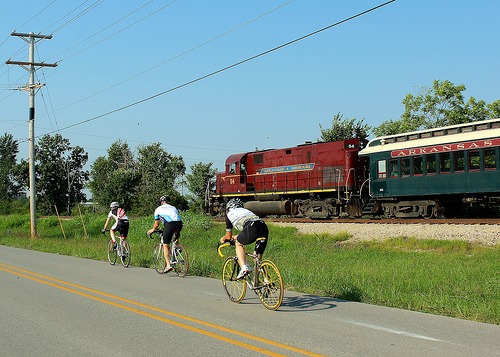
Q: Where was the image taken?
A: It was taken at the road.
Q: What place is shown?
A: It is a road.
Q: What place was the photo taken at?
A: It was taken at the road.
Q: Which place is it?
A: It is a road.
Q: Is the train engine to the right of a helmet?
A: Yes, the train engine is to the right of a helmet.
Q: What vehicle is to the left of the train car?
A: The vehicle is a locomotive.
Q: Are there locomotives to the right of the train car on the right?
A: No, the locomotive is to the left of the train car.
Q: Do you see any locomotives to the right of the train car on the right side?
A: No, the locomotive is to the left of the train car.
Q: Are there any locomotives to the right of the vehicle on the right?
A: No, the locomotive is to the left of the train car.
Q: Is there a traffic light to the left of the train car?
A: No, there is a locomotive to the left of the train car.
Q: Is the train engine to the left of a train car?
A: Yes, the train engine is to the left of a train car.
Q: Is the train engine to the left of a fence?
A: No, the train engine is to the left of a train car.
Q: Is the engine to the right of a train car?
A: No, the engine is to the left of a train car.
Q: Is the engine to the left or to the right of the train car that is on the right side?
A: The engine is to the left of the train car.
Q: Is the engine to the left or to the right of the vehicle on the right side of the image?
A: The engine is to the left of the train car.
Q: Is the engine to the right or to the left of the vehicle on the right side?
A: The engine is to the left of the train car.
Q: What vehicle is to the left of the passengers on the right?
A: The vehicle is a locomotive.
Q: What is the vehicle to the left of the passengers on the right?
A: The vehicle is a locomotive.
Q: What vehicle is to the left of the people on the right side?
A: The vehicle is a locomotive.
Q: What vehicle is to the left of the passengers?
A: The vehicle is a locomotive.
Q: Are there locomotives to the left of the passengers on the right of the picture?
A: Yes, there is a locomotive to the left of the passengers.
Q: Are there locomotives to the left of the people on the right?
A: Yes, there is a locomotive to the left of the passengers.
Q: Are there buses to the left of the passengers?
A: No, there is a locomotive to the left of the passengers.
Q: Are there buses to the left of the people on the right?
A: No, there is a locomotive to the left of the passengers.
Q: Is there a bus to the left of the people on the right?
A: No, there is a locomotive to the left of the passengers.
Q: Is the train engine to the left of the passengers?
A: Yes, the train engine is to the left of the passengers.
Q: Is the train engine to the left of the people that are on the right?
A: Yes, the train engine is to the left of the passengers.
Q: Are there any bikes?
A: Yes, there is a bike.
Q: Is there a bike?
A: Yes, there is a bike.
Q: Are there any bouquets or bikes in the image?
A: Yes, there is a bike.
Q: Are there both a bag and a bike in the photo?
A: No, there is a bike but no bags.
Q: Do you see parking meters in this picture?
A: No, there are no parking meters.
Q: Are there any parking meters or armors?
A: No, there are no parking meters or armors.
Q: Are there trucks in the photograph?
A: No, there are no trucks.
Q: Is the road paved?
A: Yes, the road is paved.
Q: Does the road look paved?
A: Yes, the road is paved.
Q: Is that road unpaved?
A: No, the road is paved.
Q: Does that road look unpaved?
A: No, the road is paved.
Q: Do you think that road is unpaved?
A: No, the road is paved.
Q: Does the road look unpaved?
A: No, the road is paved.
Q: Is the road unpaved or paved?
A: The road is paved.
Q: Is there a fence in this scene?
A: No, there are no fences.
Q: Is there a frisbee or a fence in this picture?
A: No, there are no fences or frisbees.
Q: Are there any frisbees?
A: No, there are no frisbees.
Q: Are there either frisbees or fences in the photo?
A: No, there are no frisbees or fences.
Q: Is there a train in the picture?
A: Yes, there is a train.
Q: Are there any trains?
A: Yes, there is a train.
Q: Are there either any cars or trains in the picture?
A: Yes, there is a train.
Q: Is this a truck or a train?
A: This is a train.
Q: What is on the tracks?
A: The train is on the tracks.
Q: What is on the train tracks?
A: The train is on the tracks.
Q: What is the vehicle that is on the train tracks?
A: The vehicle is a train.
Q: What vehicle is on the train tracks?
A: The vehicle is a train.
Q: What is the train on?
A: The train is on the train tracks.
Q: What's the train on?
A: The train is on the train tracks.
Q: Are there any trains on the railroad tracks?
A: Yes, there is a train on the railroad tracks.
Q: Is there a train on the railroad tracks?
A: Yes, there is a train on the railroad tracks.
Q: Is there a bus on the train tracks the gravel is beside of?
A: No, there is a train on the railroad tracks.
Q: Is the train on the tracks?
A: Yes, the train is on the tracks.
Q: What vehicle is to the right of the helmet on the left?
A: The vehicle is a train.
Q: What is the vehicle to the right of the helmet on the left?
A: The vehicle is a train.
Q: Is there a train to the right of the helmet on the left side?
A: Yes, there is a train to the right of the helmet.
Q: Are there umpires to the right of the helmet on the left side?
A: No, there is a train to the right of the helmet.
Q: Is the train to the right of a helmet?
A: Yes, the train is to the right of a helmet.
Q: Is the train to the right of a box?
A: No, the train is to the right of a helmet.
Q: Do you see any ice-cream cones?
A: No, there are no ice-cream cones.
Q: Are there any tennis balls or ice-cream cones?
A: No, there are no ice-cream cones or tennis balls.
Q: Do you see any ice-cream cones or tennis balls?
A: No, there are no ice-cream cones or tennis balls.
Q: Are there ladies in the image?
A: No, there are no ladies.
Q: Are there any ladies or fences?
A: No, there are no ladies or fences.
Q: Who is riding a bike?
A: The man is riding a bike.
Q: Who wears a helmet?
A: The man wears a helmet.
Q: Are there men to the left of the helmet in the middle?
A: Yes, there is a man to the left of the helmet.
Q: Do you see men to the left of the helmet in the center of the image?
A: Yes, there is a man to the left of the helmet.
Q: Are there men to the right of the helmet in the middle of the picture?
A: No, the man is to the left of the helmet.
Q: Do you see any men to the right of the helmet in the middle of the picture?
A: No, the man is to the left of the helmet.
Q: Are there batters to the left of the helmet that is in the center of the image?
A: No, there is a man to the left of the helmet.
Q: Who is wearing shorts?
A: The man is wearing shorts.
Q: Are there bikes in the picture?
A: Yes, there is a bike.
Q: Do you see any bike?
A: Yes, there is a bike.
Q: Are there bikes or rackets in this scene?
A: Yes, there is a bike.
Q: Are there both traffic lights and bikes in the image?
A: No, there is a bike but no traffic lights.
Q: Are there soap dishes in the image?
A: No, there are no soap dishes.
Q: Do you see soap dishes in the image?
A: No, there are no soap dishes.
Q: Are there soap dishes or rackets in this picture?
A: No, there are no soap dishes or rackets.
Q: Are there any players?
A: No, there are no players.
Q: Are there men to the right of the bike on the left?
A: Yes, there is a man to the right of the bike.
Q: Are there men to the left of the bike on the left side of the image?
A: No, the man is to the right of the bike.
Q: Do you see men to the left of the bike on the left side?
A: No, the man is to the right of the bike.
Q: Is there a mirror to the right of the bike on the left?
A: No, there is a man to the right of the bike.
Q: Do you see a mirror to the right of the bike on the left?
A: No, there is a man to the right of the bike.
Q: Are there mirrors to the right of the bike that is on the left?
A: No, there is a man to the right of the bike.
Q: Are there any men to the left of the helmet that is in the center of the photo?
A: Yes, there is a man to the left of the helmet.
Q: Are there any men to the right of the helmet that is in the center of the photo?
A: No, the man is to the left of the helmet.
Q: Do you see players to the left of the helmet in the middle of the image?
A: No, there is a man to the left of the helmet.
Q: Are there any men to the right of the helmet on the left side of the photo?
A: Yes, there is a man to the right of the helmet.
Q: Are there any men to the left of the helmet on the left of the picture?
A: No, the man is to the right of the helmet.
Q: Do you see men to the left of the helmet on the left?
A: No, the man is to the right of the helmet.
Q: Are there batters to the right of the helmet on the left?
A: No, there is a man to the right of the helmet.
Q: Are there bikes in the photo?
A: Yes, there is a bike.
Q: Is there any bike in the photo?
A: Yes, there is a bike.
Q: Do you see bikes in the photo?
A: Yes, there is a bike.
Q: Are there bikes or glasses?
A: Yes, there is a bike.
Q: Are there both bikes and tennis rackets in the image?
A: No, there is a bike but no rackets.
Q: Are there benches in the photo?
A: No, there are no benches.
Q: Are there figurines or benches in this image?
A: No, there are no benches or figurines.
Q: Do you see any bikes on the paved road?
A: Yes, there is a bike on the road.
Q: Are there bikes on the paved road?
A: Yes, there is a bike on the road.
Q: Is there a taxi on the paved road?
A: No, there is a bike on the road.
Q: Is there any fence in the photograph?
A: No, there are no fences.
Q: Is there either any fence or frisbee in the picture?
A: No, there are no fences or frisbees.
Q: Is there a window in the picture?
A: Yes, there are windows.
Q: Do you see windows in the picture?
A: Yes, there are windows.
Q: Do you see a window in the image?
A: Yes, there are windows.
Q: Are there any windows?
A: Yes, there are windows.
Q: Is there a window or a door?
A: Yes, there are windows.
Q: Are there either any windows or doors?
A: Yes, there are windows.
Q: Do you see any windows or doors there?
A: Yes, there are windows.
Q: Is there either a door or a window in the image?
A: Yes, there are windows.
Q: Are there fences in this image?
A: No, there are no fences.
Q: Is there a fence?
A: No, there are no fences.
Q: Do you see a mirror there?
A: No, there are no mirrors.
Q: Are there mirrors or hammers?
A: No, there are no mirrors or hammers.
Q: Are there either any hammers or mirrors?
A: No, there are no mirrors or hammers.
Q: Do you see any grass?
A: Yes, there is grass.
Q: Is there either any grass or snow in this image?
A: Yes, there is grass.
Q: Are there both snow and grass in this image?
A: No, there is grass but no snow.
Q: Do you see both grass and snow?
A: No, there is grass but no snow.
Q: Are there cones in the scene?
A: No, there are no cones.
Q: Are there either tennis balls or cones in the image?
A: No, there are no cones or tennis balls.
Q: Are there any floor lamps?
A: No, there are no floor lamps.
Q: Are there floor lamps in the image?
A: No, there are no floor lamps.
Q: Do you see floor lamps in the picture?
A: No, there are no floor lamps.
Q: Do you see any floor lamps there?
A: No, there are no floor lamps.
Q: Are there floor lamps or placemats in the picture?
A: No, there are no floor lamps or placemats.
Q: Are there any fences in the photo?
A: No, there are no fences.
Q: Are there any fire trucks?
A: No, there are no fire trucks.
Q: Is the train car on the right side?
A: Yes, the train car is on the right of the image.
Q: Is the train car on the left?
A: No, the train car is on the right of the image.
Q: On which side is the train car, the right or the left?
A: The train car is on the right of the image.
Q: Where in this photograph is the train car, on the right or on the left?
A: The train car is on the right of the image.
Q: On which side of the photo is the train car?
A: The train car is on the right of the image.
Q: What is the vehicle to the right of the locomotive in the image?
A: The vehicle is a train car.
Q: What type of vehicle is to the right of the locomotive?
A: The vehicle is a train car.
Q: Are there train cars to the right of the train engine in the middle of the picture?
A: Yes, there is a train car to the right of the train engine.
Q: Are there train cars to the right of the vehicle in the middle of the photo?
A: Yes, there is a train car to the right of the train engine.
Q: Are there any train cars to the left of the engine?
A: No, the train car is to the right of the engine.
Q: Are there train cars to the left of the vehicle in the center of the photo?
A: No, the train car is to the right of the engine.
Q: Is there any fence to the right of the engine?
A: No, there is a train car to the right of the engine.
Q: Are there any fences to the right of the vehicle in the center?
A: No, there is a train car to the right of the engine.